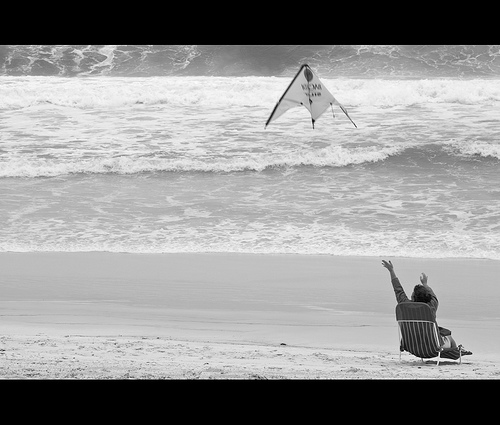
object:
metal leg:
[399, 349, 462, 366]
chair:
[395, 302, 472, 367]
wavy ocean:
[0, 43, 500, 260]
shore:
[0, 300, 500, 380]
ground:
[0, 303, 499, 379]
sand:
[0, 334, 500, 380]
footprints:
[0, 332, 499, 378]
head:
[411, 284, 431, 303]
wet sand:
[27, 259, 310, 299]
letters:
[302, 83, 323, 96]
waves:
[0, 45, 500, 178]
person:
[382, 259, 457, 348]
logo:
[302, 84, 321, 96]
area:
[0, 334, 499, 379]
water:
[12, 46, 242, 256]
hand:
[381, 259, 393, 270]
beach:
[0, 250, 499, 380]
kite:
[263, 64, 357, 130]